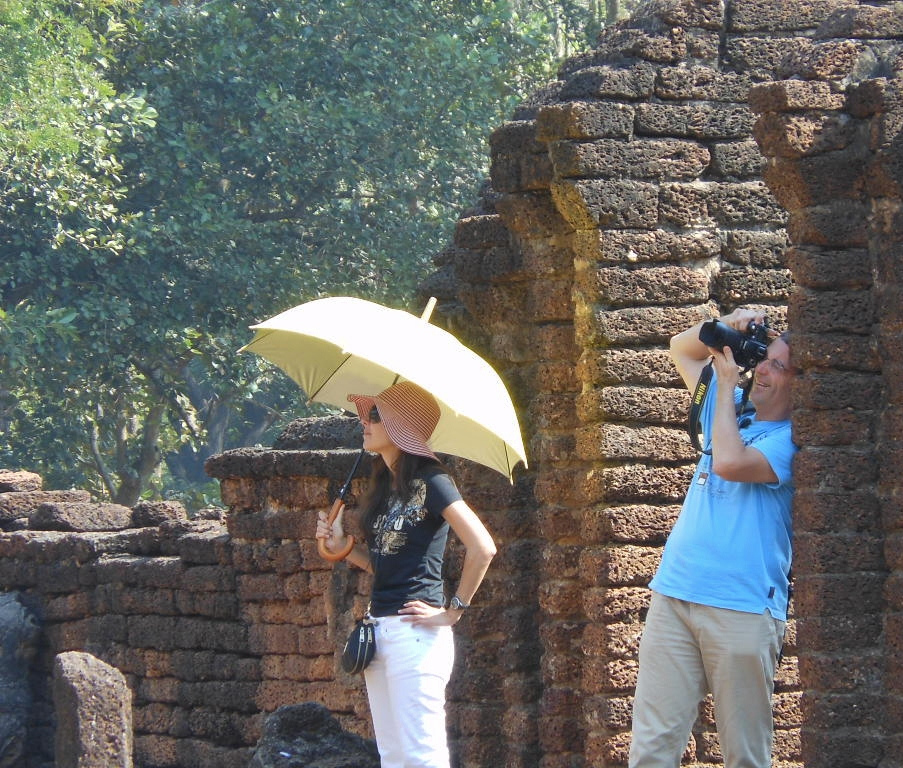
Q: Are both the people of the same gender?
A: No, they are both male and female.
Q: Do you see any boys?
A: No, there are no boys.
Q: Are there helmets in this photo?
A: No, there are no helmets.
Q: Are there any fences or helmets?
A: No, there are no helmets or fences.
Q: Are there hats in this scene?
A: Yes, there is a hat.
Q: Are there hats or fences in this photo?
A: Yes, there is a hat.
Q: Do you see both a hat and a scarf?
A: No, there is a hat but no scarves.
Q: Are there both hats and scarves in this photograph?
A: No, there is a hat but no scarves.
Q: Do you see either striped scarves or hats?
A: Yes, there is a striped hat.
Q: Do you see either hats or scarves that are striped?
A: Yes, the hat is striped.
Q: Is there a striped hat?
A: Yes, there is a striped hat.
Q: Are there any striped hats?
A: Yes, there is a striped hat.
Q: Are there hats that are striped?
A: Yes, there is a hat that is striped.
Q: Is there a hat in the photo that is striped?
A: Yes, there is a hat that is striped.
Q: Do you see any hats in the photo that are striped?
A: Yes, there is a hat that is striped.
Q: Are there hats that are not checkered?
A: Yes, there is a striped hat.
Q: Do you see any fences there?
A: No, there are no fences.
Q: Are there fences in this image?
A: No, there are no fences.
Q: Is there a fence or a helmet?
A: No, there are no fences or helmets.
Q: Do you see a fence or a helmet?
A: No, there are no fences or helmets.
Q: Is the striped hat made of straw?
A: Yes, the hat is made of straw.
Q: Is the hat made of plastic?
A: No, the hat is made of straw.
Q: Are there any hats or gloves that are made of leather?
A: No, there is a hat but it is made of straw.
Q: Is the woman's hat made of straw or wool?
A: The hat is made of straw.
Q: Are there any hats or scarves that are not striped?
A: No, there is a hat but it is striped.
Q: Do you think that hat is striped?
A: Yes, the hat is striped.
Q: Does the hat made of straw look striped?
A: Yes, the hat is striped.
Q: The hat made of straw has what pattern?
A: The hat is striped.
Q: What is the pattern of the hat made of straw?
A: The hat is striped.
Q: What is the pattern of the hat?
A: The hat is striped.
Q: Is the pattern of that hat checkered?
A: No, the hat is striped.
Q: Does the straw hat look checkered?
A: No, the hat is striped.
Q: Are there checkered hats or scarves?
A: No, there is a hat but it is striped.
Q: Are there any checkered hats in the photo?
A: No, there is a hat but it is striped.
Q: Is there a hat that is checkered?
A: No, there is a hat but it is striped.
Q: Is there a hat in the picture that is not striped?
A: No, there is a hat but it is striped.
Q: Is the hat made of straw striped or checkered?
A: The hat is striped.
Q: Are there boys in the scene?
A: No, there are no boys.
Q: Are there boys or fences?
A: No, there are no boys or fences.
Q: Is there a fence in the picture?
A: No, there are no fences.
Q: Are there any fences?
A: No, there are no fences.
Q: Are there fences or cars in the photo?
A: No, there are no fences or cars.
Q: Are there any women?
A: Yes, there is a woman.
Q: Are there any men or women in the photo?
A: Yes, there is a woman.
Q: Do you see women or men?
A: Yes, there is a woman.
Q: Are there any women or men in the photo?
A: Yes, there is a woman.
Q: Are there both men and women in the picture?
A: Yes, there are both a woman and a man.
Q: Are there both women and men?
A: Yes, there are both a woman and a man.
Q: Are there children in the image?
A: No, there are no children.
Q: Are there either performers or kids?
A: No, there are no kids or performers.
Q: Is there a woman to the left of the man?
A: Yes, there is a woman to the left of the man.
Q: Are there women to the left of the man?
A: Yes, there is a woman to the left of the man.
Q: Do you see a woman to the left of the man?
A: Yes, there is a woman to the left of the man.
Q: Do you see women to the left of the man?
A: Yes, there is a woman to the left of the man.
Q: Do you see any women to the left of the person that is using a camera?
A: Yes, there is a woman to the left of the man.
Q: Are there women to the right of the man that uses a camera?
A: No, the woman is to the left of the man.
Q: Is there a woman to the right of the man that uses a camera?
A: No, the woman is to the left of the man.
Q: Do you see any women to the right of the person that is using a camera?
A: No, the woman is to the left of the man.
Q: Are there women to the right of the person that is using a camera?
A: No, the woman is to the left of the man.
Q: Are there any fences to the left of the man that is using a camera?
A: No, there is a woman to the left of the man.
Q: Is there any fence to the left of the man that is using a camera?
A: No, there is a woman to the left of the man.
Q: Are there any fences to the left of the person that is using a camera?
A: No, there is a woman to the left of the man.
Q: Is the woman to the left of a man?
A: Yes, the woman is to the left of a man.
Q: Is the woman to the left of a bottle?
A: No, the woman is to the left of a man.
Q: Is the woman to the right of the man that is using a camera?
A: No, the woman is to the left of the man.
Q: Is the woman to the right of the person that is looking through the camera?
A: No, the woman is to the left of the man.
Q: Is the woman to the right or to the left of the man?
A: The woman is to the left of the man.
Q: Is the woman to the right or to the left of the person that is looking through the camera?
A: The woman is to the left of the man.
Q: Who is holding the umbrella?
A: The woman is holding the umbrella.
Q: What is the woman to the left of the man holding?
A: The woman is holding the umbrella.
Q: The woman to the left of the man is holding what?
A: The woman is holding the umbrella.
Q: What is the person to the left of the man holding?
A: The woman is holding the umbrella.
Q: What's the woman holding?
A: The woman is holding the umbrella.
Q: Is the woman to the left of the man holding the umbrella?
A: Yes, the woman is holding the umbrella.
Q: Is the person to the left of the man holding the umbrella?
A: Yes, the woman is holding the umbrella.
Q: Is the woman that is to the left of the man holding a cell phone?
A: No, the woman is holding the umbrella.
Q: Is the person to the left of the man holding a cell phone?
A: No, the woman is holding the umbrella.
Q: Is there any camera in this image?
A: Yes, there is a camera.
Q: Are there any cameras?
A: Yes, there is a camera.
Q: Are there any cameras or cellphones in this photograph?
A: Yes, there is a camera.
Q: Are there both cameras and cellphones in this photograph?
A: No, there is a camera but no cell phones.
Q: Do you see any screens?
A: No, there are no screens.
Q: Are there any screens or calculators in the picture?
A: No, there are no screens or calculators.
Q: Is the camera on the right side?
A: Yes, the camera is on the right of the image.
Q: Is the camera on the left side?
A: No, the camera is on the right of the image.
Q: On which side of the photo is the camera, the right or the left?
A: The camera is on the right of the image.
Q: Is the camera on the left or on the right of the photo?
A: The camera is on the right of the image.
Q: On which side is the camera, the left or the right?
A: The camera is on the right of the image.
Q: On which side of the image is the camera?
A: The camera is on the right of the image.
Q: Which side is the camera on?
A: The camera is on the right of the image.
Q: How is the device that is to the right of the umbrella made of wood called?
A: The device is a camera.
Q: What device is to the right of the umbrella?
A: The device is a camera.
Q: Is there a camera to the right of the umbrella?
A: Yes, there is a camera to the right of the umbrella.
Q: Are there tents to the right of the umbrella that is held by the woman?
A: No, there is a camera to the right of the umbrella.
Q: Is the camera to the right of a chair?
A: No, the camera is to the right of the umbrella.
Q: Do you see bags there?
A: Yes, there is a bag.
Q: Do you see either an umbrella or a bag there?
A: Yes, there is a bag.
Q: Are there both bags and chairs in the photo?
A: No, there is a bag but no chairs.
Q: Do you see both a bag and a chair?
A: No, there is a bag but no chairs.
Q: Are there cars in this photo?
A: No, there are no cars.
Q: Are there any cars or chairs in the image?
A: No, there are no cars or chairs.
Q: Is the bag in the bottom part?
A: Yes, the bag is in the bottom of the image.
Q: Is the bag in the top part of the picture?
A: No, the bag is in the bottom of the image.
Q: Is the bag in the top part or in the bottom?
A: The bag is in the bottom of the image.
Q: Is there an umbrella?
A: Yes, there is an umbrella.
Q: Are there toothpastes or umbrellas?
A: Yes, there is an umbrella.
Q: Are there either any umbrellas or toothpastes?
A: Yes, there is an umbrella.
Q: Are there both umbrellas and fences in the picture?
A: No, there is an umbrella but no fences.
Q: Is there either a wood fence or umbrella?
A: Yes, there is a wood umbrella.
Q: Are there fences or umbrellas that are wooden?
A: Yes, the umbrella is wooden.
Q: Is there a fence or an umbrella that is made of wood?
A: Yes, the umbrella is made of wood.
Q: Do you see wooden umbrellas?
A: Yes, there is a wood umbrella.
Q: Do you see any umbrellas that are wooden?
A: Yes, there is an umbrella that is wooden.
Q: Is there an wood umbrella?
A: Yes, there is an umbrella that is made of wood.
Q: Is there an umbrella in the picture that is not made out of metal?
A: Yes, there is an umbrella that is made of wood.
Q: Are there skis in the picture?
A: No, there are no skis.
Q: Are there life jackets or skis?
A: No, there are no skis or life jackets.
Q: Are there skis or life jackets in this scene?
A: No, there are no skis or life jackets.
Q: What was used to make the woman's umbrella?
A: The umbrella is made of wood.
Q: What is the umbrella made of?
A: The umbrella is made of wood.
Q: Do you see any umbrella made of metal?
A: No, there is an umbrella but it is made of wood.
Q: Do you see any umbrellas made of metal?
A: No, there is an umbrella but it is made of wood.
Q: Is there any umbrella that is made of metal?
A: No, there is an umbrella but it is made of wood.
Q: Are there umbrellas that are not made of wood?
A: No, there is an umbrella but it is made of wood.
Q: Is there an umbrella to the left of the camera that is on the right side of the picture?
A: Yes, there is an umbrella to the left of the camera.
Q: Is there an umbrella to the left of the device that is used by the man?
A: Yes, there is an umbrella to the left of the camera.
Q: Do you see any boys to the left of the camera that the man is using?
A: No, there is an umbrella to the left of the camera.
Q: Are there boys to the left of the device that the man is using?
A: No, there is an umbrella to the left of the camera.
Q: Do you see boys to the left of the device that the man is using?
A: No, there is an umbrella to the left of the camera.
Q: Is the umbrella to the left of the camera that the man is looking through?
A: Yes, the umbrella is to the left of the camera.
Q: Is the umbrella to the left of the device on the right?
A: Yes, the umbrella is to the left of the camera.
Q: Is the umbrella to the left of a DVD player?
A: No, the umbrella is to the left of the camera.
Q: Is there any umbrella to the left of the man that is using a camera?
A: Yes, there is an umbrella to the left of the man.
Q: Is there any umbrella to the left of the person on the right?
A: Yes, there is an umbrella to the left of the man.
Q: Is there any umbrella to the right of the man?
A: No, the umbrella is to the left of the man.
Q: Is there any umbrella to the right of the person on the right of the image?
A: No, the umbrella is to the left of the man.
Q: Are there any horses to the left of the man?
A: No, there is an umbrella to the left of the man.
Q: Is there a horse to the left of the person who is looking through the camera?
A: No, there is an umbrella to the left of the man.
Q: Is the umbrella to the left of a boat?
A: No, the umbrella is to the left of the man.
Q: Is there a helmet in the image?
A: No, there are no helmets.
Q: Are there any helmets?
A: No, there are no helmets.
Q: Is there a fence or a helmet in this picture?
A: No, there are no helmets or fences.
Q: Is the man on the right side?
A: Yes, the man is on the right of the image.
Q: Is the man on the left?
A: No, the man is on the right of the image.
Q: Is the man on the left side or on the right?
A: The man is on the right of the image.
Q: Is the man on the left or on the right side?
A: The man is on the right of the image.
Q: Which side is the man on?
A: The man is on the right of the image.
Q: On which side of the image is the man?
A: The man is on the right of the image.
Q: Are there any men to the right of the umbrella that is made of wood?
A: Yes, there is a man to the right of the umbrella.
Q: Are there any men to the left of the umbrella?
A: No, the man is to the right of the umbrella.